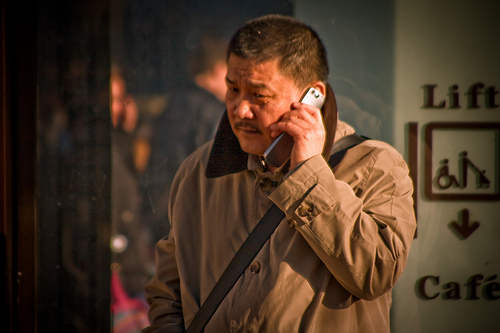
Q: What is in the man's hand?
A: His phone.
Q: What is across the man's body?
A: The strap to his bag.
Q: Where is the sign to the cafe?
A: On the right.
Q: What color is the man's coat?
A: Brown.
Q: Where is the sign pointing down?
A: Behind the man, to the right.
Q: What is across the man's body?
A: The strap to his bag.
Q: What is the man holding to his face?
A: His phone.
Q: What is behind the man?
A: A glass window.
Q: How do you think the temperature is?
A: Cold.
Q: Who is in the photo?
A: A man.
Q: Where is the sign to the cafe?
A: On the right.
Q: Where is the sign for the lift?
A: Behind the man, on the right.